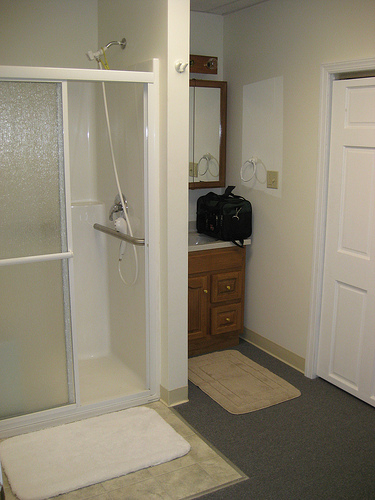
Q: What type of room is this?
A: It is a bathroom.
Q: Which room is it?
A: It is a bathroom.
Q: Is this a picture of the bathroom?
A: Yes, it is showing the bathroom.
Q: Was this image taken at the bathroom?
A: Yes, it was taken in the bathroom.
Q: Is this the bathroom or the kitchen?
A: It is the bathroom.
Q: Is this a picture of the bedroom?
A: No, the picture is showing the bathroom.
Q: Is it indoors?
A: Yes, it is indoors.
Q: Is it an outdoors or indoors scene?
A: It is indoors.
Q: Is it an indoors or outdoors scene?
A: It is indoors.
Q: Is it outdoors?
A: No, it is indoors.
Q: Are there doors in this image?
A: Yes, there is a door.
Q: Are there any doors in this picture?
A: Yes, there is a door.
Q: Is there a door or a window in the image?
A: Yes, there is a door.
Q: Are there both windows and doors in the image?
A: No, there is a door but no windows.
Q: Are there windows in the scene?
A: No, there are no windows.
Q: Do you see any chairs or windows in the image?
A: No, there are no windows or chairs.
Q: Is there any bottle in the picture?
A: No, there are no bottles.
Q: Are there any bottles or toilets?
A: No, there are no bottles or toilets.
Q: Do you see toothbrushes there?
A: No, there are no toothbrushes.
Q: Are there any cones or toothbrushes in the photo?
A: No, there are no toothbrushes or cones.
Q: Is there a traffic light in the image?
A: No, there are no traffic lights.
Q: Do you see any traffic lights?
A: No, there are no traffic lights.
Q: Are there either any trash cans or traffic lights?
A: No, there are no traffic lights or trash cans.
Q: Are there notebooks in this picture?
A: No, there are no notebooks.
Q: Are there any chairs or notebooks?
A: No, there are no notebooks or chairs.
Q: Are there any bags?
A: Yes, there is a bag.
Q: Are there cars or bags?
A: Yes, there is a bag.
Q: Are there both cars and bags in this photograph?
A: No, there is a bag but no cars.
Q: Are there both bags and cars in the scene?
A: No, there is a bag but no cars.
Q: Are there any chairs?
A: No, there are no chairs.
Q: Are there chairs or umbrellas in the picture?
A: No, there are no chairs or umbrellas.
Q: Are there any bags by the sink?
A: Yes, there is a bag by the sink.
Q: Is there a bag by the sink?
A: Yes, there is a bag by the sink.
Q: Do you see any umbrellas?
A: No, there are no umbrellas.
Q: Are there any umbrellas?
A: No, there are no umbrellas.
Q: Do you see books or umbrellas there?
A: No, there are no umbrellas or books.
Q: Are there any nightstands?
A: No, there are no nightstands.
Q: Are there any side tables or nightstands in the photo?
A: No, there are no nightstands or side tables.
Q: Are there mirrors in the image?
A: Yes, there is a mirror.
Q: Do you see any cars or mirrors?
A: Yes, there is a mirror.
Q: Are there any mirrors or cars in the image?
A: Yes, there is a mirror.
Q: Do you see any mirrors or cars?
A: Yes, there is a mirror.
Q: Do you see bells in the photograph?
A: No, there are no bells.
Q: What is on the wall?
A: The mirror is on the wall.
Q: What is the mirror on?
A: The mirror is on the wall.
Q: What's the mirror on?
A: The mirror is on the wall.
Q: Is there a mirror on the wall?
A: Yes, there is a mirror on the wall.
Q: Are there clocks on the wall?
A: No, there is a mirror on the wall.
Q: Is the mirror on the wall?
A: Yes, the mirror is on the wall.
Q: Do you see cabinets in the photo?
A: Yes, there is a cabinet.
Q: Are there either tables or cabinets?
A: Yes, there is a cabinet.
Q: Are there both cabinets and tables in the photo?
A: No, there is a cabinet but no tables.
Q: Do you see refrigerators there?
A: No, there are no refrigerators.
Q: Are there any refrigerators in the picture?
A: No, there are no refrigerators.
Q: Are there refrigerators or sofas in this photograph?
A: No, there are no refrigerators or sofas.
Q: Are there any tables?
A: No, there are no tables.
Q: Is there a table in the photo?
A: No, there are no tables.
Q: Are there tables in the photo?
A: No, there are no tables.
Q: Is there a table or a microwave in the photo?
A: No, there are no tables or microwaves.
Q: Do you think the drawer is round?
A: Yes, the drawer is round.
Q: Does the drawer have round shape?
A: Yes, the drawer is round.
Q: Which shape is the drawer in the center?
A: The drawer is round.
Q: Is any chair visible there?
A: No, there are no chairs.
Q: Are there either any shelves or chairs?
A: No, there are no chairs or shelves.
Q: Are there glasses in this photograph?
A: No, there are no glasses.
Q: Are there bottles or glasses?
A: No, there are no glasses or bottles.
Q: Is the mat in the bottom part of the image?
A: Yes, the mat is in the bottom of the image.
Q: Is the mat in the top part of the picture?
A: No, the mat is in the bottom of the image.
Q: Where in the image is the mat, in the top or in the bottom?
A: The mat is in the bottom of the image.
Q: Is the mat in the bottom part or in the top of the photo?
A: The mat is in the bottom of the image.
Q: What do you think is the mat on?
A: The mat is on the carpet.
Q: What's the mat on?
A: The mat is on the carpet.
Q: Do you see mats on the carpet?
A: Yes, there is a mat on the carpet.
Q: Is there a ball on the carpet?
A: No, there is a mat on the carpet.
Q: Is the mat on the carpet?
A: Yes, the mat is on the carpet.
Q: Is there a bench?
A: No, there are no benches.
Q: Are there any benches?
A: No, there are no benches.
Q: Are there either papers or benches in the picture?
A: No, there are no benches or papers.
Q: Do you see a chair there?
A: No, there are no chairs.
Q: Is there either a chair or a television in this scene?
A: No, there are no chairs or televisions.